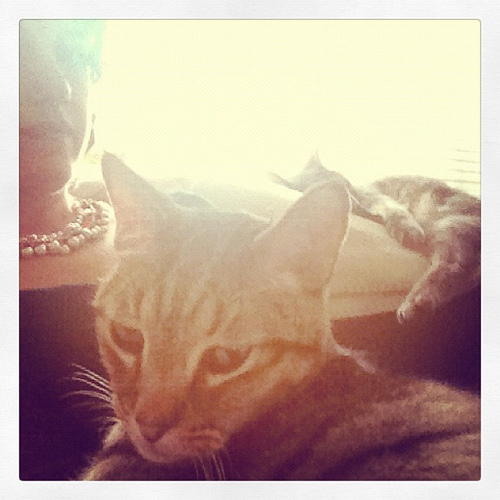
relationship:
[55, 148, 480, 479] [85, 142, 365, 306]
cat has ears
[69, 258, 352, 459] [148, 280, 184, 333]
cat has stripes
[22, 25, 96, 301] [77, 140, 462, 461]
woman looking at cat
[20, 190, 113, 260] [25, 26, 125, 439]
necklace on body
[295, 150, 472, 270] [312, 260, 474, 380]
cat on furniture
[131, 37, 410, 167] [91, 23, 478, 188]
sun shining through window